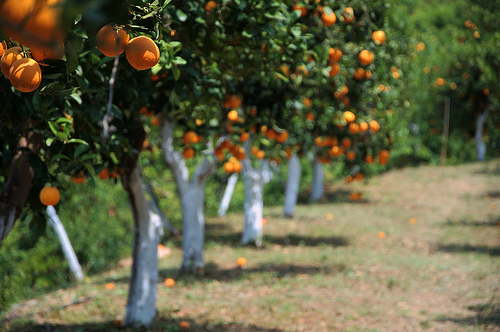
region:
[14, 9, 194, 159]
a group of oranges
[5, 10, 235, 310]
tall orange trees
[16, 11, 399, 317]
a group of tall orange trees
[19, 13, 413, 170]
oranges hanging in a tree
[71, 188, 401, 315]
oranges on the ground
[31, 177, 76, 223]
one orange hanging in a tree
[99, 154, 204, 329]
thick branch of the tree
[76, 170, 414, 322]
the ground with oranges on it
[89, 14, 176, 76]
a pair of oranges in a tree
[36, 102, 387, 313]
the tree branches of the trees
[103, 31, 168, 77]
fruits hanging from the tree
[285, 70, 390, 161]
fruits hanging from the tree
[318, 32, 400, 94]
fruits hanging from the tree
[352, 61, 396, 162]
fruits hanging from the tree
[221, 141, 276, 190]
fruits hanging from the tree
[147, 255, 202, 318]
fruits on the ground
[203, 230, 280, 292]
fruits on the ground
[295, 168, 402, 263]
fruits on the ground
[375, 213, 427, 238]
fruits on the ground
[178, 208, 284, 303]
fruits on the ground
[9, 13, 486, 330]
trees that have oranges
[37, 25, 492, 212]
oranges on trees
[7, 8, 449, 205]
oranges that are on trees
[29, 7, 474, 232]
oranges that are outside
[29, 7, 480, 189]
oranges growing on trees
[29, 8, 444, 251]
trees that are going oranges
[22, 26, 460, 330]
orange trees in a line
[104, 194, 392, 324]
oranges falling on the ground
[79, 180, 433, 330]
a ground with oranges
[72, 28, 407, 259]
Oranges are growing on trees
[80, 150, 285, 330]
The tree leaves have oranges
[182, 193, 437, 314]
The ground has oranges on it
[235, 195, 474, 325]
The ground has dead grass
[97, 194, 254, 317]
The tree bark is white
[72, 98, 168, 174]
The tree leaves are green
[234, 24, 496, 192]
Several orange trees are in the garden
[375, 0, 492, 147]
Orange trees are in the distance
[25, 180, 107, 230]
A single orange is on the branch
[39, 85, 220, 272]
The oranges are orange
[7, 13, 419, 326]
a line of orange trees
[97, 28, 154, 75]
oranges on a tree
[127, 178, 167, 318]
a white tree trunk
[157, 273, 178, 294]
a orange on the ground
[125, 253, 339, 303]
shadow of a tree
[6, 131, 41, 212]
limb of a tree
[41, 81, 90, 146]
green leaves on a tree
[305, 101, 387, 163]
a group of oranges on a tree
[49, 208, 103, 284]
a white pipe in the ground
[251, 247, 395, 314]
green and brown grass